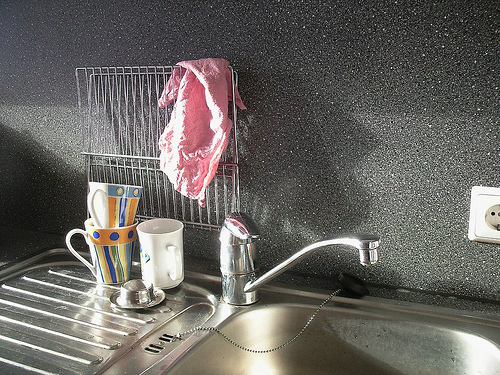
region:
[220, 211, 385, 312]
the faucet is silver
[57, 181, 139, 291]
the cups are stacked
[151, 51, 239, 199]
the cloth is pink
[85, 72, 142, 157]
the rack is white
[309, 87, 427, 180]
the wall is gray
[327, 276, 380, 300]
the stopper is black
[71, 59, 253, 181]
the cloth is on a rack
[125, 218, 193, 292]
the cup is white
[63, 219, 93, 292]
the cup has a handle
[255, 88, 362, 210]
the shadow is on the wall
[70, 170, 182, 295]
Three coffee cups at the sink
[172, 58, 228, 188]
Pink wash rag at the sink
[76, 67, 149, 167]
Wire rack hanging on the wall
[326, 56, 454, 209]
Gray granite wall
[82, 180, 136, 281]
Two cups alike on the sink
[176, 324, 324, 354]
Chain on the sink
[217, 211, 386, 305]
Water spout on the sink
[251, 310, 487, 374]
Stainless steel sink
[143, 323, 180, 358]
Four drain holes at the sink top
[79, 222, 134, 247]
Bottom cup has blue dots around the top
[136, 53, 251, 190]
a pink towl on a rack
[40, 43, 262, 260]
a silver wire rack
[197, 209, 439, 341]
a silver water faucet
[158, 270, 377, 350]
a chain attached to plug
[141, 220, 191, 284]
a white coffee cup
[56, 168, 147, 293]
one cup stacked in the other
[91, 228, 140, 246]
dark blue dots on cup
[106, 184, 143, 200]
two yellow dots on cup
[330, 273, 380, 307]
black plug for sink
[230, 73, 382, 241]
shadow on wall from towel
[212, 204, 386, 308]
Shiny silver sink faucet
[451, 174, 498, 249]
Outlet on the wall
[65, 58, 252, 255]
Silver rack against wall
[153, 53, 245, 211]
Pink towel hanging on rack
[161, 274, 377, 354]
Stopper attached to sink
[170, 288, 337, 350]
Silver chain on stopper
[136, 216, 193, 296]
White coffee mug on side of sink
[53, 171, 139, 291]
identical mugs stacked together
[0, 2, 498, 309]
Gray granite covered wall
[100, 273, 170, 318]
Silver lid on sink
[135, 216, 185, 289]
a white cup on the drainboard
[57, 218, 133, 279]
a striped cup on the drainboard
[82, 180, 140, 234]
a cup stacked on the other cup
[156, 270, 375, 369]
a plug for the sink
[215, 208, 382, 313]
a metal faucet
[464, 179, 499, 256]
a plug behind the sink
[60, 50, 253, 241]
a folded wire rack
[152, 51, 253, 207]
a cloth on the rack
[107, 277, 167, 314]
a metal dish on the drainboard